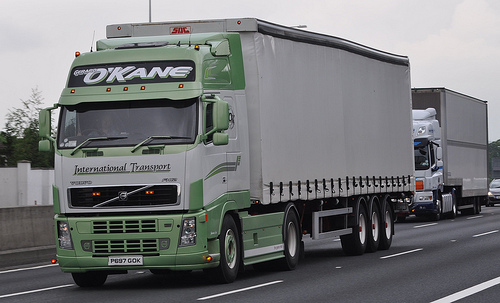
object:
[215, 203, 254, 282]
tire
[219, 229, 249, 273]
rim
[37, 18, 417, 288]
semi truck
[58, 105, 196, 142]
windshield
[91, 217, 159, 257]
grille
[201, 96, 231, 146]
side mirror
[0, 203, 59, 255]
barrier wall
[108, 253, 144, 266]
license plate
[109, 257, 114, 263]
letters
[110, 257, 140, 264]
writing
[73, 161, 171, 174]
international transport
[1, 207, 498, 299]
street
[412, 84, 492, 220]
semi truck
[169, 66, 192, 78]
letters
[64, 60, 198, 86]
back ground